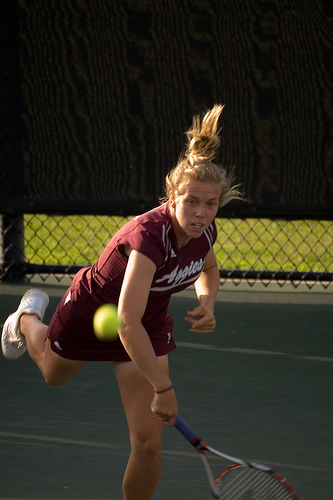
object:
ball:
[91, 303, 121, 337]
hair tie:
[154, 383, 174, 394]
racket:
[173, 413, 300, 498]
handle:
[173, 417, 209, 453]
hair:
[163, 101, 239, 204]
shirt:
[78, 199, 220, 311]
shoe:
[2, 289, 53, 362]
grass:
[24, 214, 331, 273]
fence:
[1, 205, 332, 293]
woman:
[2, 100, 251, 499]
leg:
[17, 291, 90, 389]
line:
[174, 340, 331, 363]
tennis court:
[2, 280, 331, 499]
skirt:
[45, 263, 180, 361]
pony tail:
[185, 103, 225, 161]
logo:
[152, 257, 206, 291]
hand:
[151, 389, 180, 427]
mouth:
[189, 221, 205, 232]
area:
[0, 193, 332, 497]